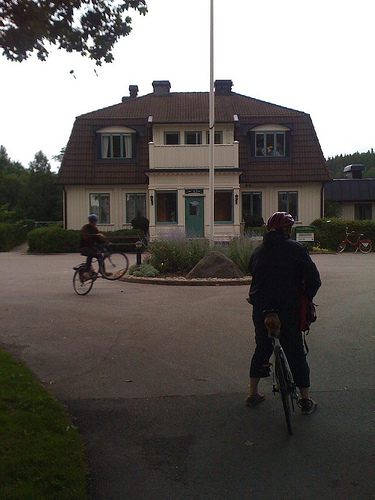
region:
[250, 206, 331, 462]
A woman riding her bike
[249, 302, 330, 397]
The woman is wearing jean capri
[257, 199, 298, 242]
The woman is wearing a helmet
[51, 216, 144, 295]
A boy does a wheelie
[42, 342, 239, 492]
Sidewalk has a huge crack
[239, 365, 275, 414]
The woman is wearing tennis shoes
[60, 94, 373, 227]
The house sits in the background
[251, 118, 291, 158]
The window is on top of the house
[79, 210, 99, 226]
The boy is wearing a blue helmet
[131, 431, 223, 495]
A oil stain is on the pavement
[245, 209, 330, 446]
person stopped on a bicycle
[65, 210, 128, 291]
person popping a wheelie on a bicycle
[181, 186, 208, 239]
green front door on a yellow house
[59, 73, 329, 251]
large yellow house with a green front door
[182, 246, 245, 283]
large rock in a flower bed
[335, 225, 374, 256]
red bicycle parked by a hedge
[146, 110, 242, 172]
second story balcony of a yellow house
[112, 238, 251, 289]
round stone lined flower bed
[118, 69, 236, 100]
three chimneys on top of house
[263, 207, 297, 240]
person wearing a bicycle helmet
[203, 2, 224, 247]
a tall white pole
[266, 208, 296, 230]
a red bike helmet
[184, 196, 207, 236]
a green front door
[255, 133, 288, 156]
a window of a home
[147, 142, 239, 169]
a beige wooden balcony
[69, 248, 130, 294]
a bike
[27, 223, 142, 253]
a long green bush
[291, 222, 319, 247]
a green and white sign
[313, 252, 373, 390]
part of a concrete driveway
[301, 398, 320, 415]
the tennis shoe of a person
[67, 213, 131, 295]
A person riding a wheelie on a bike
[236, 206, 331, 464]
A person standing on a bike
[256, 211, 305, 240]
A red bike helmet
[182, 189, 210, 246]
A green front door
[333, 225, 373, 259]
A red girl's bike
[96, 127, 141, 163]
A window with white curtains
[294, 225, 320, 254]
A white sign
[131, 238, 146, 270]
A light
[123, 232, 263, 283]
A round flower garden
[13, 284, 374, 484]
A paved street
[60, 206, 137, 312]
A man performing a trick on a bicycle.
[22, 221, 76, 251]
A bush.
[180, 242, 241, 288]
A large rock.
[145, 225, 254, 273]
Various types of flowers.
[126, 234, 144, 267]
An outdoor light fixture.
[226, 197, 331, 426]
The woman is straddling the bike.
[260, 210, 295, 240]
The woman is wearing a helmet.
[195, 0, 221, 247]
A large flag pole.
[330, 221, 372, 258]
A parked red bicycle.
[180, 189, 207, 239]
A green door.